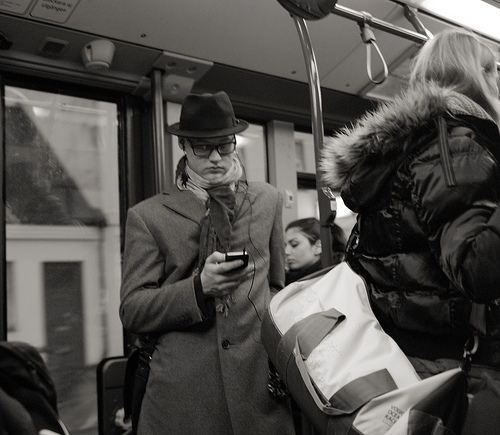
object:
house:
[0, 83, 128, 388]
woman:
[281, 215, 349, 289]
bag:
[256, 259, 473, 435]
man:
[114, 86, 305, 435]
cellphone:
[224, 251, 250, 269]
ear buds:
[177, 135, 187, 152]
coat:
[322, 83, 500, 435]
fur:
[398, 100, 420, 123]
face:
[282, 227, 307, 271]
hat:
[166, 91, 250, 139]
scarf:
[196, 183, 239, 316]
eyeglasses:
[193, 141, 238, 157]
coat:
[117, 177, 295, 435]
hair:
[441, 41, 468, 64]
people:
[314, 28, 499, 435]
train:
[0, 0, 500, 435]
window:
[0, 79, 122, 231]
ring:
[363, 36, 389, 86]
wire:
[247, 215, 254, 245]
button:
[222, 339, 233, 351]